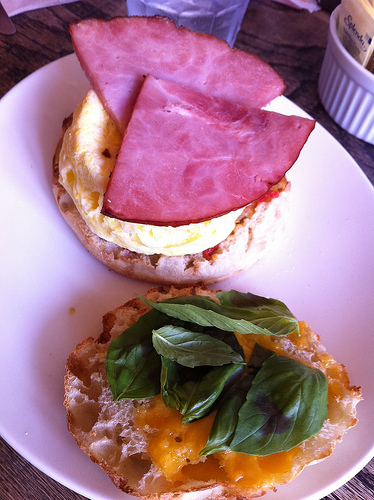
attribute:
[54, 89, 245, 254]
egg — cooked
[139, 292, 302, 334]
leaf — green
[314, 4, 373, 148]
bowl — white ceramic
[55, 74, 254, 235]
english muffin — toasted, slice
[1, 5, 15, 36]
knife — stainless , steel 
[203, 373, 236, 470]
leaf — green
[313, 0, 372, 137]
container — white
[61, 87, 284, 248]
egg — scrambled, folded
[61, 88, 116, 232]
egg — yellow , round 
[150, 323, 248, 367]
leaf — green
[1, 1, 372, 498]
table — wooden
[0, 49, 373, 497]
plate — oval, white, ceramic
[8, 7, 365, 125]
table — wooden, laminate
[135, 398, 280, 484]
cheddar cheese — melted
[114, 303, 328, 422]
leaves —  fresh,   whole,  green,  basil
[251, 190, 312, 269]
clock — toasted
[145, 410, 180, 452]
jam — orange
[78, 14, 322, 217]
bacon — canadian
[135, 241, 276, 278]
biscuit — cut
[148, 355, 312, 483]
cheese — melted, cheddar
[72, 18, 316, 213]
ham — sliced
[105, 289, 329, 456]
spinach — leaves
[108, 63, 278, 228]
meat — ham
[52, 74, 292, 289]
muffin — slice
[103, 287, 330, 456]
leaves — green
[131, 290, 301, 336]
leaf — green